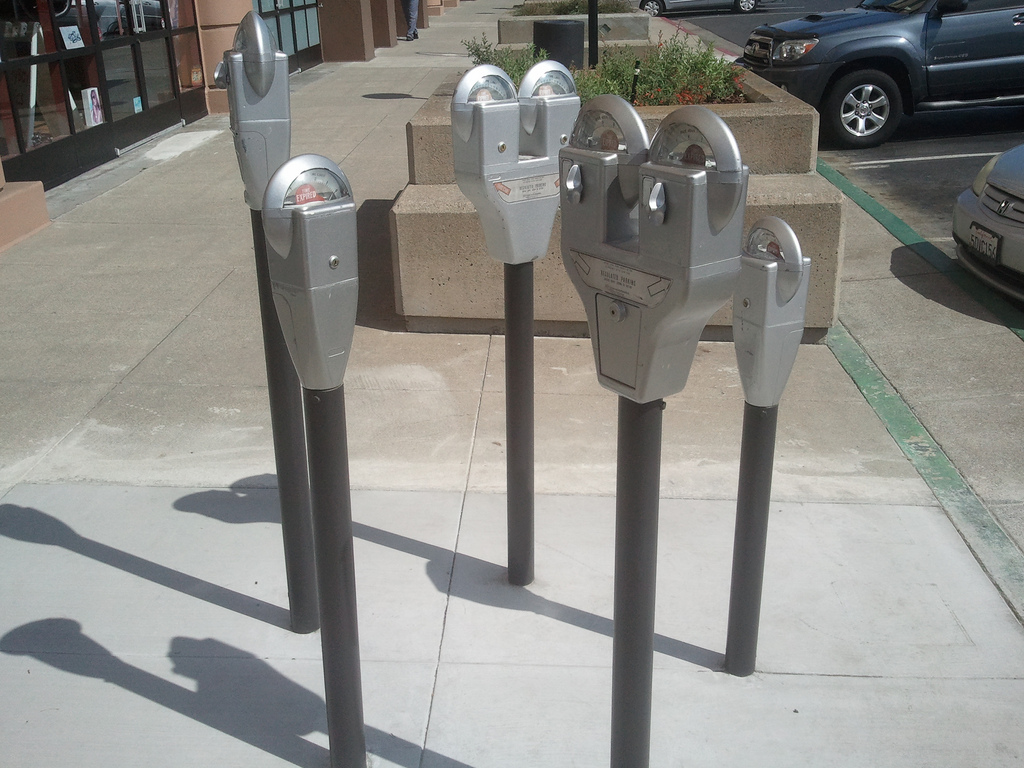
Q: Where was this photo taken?
A: On a city sidewalk.